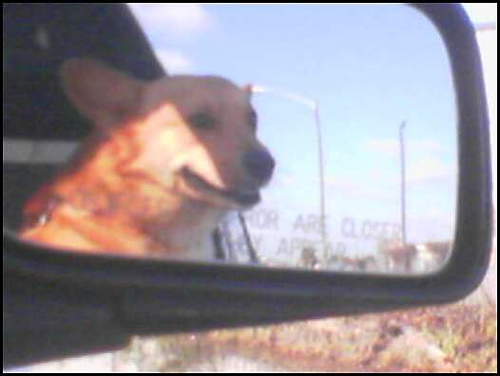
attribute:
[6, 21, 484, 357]
car — drivers side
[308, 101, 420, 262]
pole — silver 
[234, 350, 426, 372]
road — side 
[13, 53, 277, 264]
dog — reflection ,  rear view mirror , brown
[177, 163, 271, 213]
mouth — open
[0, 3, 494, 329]
mirror — rear view 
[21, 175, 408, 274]
printed mirror —  OBJECTS IN MIRROR ARE CLOSER THEN THEY APPEAR 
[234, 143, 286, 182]
nose — black , dogs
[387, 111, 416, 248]
light — street 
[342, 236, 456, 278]
building — white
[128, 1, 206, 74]
cloud — white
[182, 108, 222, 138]
eye — brown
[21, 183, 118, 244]
collar — red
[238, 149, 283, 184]
dog nose — black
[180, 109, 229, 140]
dog eye — black, brown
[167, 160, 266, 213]
dog's mouth — black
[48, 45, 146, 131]
dog ear — brown, big, pointy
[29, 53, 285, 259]
brownish dog — golden brownish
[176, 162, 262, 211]
mouth — dog's, little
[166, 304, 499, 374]
road grasses — alongside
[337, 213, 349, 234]
letter — gray, C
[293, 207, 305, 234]
letter — gray, A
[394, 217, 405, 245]
letter — gray, R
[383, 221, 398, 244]
letter — gray, E